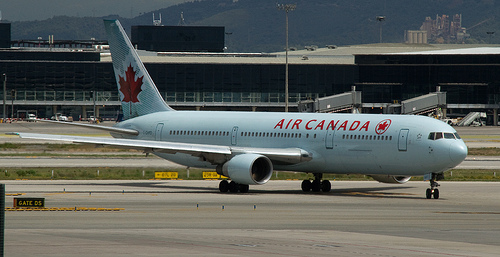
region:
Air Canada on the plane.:
[257, 107, 368, 147]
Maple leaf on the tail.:
[111, 64, 151, 118]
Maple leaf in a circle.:
[372, 111, 396, 144]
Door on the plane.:
[314, 117, 344, 153]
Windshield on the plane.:
[422, 117, 467, 155]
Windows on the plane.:
[166, 125, 328, 152]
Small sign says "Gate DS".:
[13, 189, 46, 213]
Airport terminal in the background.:
[3, 37, 499, 130]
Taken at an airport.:
[6, 16, 498, 245]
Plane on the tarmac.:
[10, 172, 495, 250]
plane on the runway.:
[61, 0, 403, 255]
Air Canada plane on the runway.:
[226, 75, 454, 170]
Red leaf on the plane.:
[120, 52, 162, 123]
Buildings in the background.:
[145, 8, 486, 158]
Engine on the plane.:
[132, 129, 427, 232]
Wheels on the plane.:
[275, 166, 415, 208]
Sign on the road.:
[15, 182, 251, 240]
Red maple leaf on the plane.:
[74, 26, 488, 196]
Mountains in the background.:
[89, 7, 469, 107]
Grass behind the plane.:
[41, 157, 221, 200]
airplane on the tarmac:
[18, 16, 473, 224]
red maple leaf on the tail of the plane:
[111, 60, 152, 117]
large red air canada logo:
[272, 108, 397, 136]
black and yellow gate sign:
[9, 193, 54, 210]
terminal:
[4, 18, 487, 118]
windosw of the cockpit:
[421, 128, 462, 142]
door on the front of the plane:
[392, 126, 412, 156]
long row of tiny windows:
[168, 128, 391, 145]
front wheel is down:
[423, 179, 448, 201]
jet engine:
[215, 151, 271, 187]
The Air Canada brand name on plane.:
[275, 119, 367, 134]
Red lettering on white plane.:
[275, 114, 370, 133]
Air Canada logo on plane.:
[372, 117, 389, 134]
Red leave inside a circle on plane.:
[374, 117, 392, 135]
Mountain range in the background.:
[182, 4, 420, 41]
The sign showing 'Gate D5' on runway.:
[15, 196, 47, 206]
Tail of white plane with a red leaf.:
[107, 16, 170, 121]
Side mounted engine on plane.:
[220, 156, 272, 184]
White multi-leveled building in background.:
[405, 28, 426, 41]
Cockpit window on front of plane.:
[427, 132, 463, 140]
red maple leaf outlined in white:
[107, 52, 149, 116]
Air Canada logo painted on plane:
[271, 111, 393, 142]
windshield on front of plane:
[426, 127, 463, 144]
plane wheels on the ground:
[198, 163, 455, 215]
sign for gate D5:
[11, 192, 48, 210]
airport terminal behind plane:
[1, 6, 495, 210]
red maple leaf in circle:
[372, 116, 395, 134]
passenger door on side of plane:
[393, 123, 411, 155]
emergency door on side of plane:
[226, 121, 240, 147]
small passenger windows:
[239, 126, 304, 143]